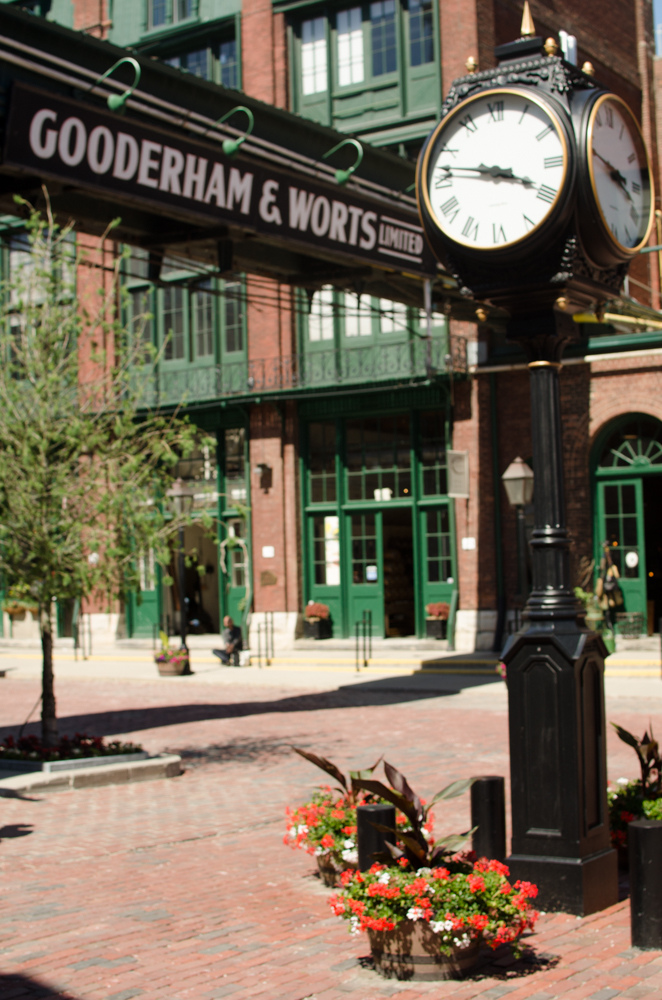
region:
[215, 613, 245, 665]
a man sitting on a step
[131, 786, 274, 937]
a red brick walk way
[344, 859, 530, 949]
a batch of red and white flowers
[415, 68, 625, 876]
a clock on a post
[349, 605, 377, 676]
a black hand rail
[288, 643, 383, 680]
a set of concrete step painted yellow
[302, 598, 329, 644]
a potted plant next to a building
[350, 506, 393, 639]
a green wood door to a building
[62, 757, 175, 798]
a concrete curb around a tree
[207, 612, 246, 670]
a man sitting down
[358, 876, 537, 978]
a round wood pot with flowers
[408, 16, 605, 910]
a clock on a black post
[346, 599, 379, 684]
a metal handrail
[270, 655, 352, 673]
concrete steps painted yellow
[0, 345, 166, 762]
a small tree with green leaves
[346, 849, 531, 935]
red and white flowers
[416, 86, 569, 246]
The clock facing more left and center than right.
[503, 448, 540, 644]
The lamp post by the door.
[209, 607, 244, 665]
The man sitting on the stairs.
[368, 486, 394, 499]
The white numbers above the door.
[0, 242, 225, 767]
The tree on the left.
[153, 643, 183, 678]
The potted plant next to the man.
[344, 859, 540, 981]
The potted plant in front of the post the clock is mounted on.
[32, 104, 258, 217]
The name GOODERHAM on the sign.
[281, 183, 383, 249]
The word WORTS on the sign.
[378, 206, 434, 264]
The word LIMITED on the sign.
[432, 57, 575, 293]
White clock face pointing to the left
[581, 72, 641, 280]
White clock facing the right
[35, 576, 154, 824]
Curbing around the tree in the parking lot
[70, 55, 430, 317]
Billboard hanging above the street in the lot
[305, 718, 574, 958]
Flowers planted at the base of the pole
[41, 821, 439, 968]
Brick sidewalk in front of the plants and the pole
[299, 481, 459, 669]
Large entry way in front of the store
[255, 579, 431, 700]
Stairs in front of the entry way of the store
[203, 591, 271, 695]
Man sitting on the steps outside of the building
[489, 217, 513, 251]
A number on a clock.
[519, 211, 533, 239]
A number on a clock.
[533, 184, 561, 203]
A number on a clock.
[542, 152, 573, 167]
A number on a clock.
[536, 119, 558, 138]
A number on a clock.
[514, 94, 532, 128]
A number on a clock.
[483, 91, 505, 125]
A number on a clock.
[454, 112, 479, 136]
A number on a clock.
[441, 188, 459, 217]
A number on a clock.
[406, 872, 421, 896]
flower in a pot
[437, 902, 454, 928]
flower in a pot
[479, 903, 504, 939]
flower in a pot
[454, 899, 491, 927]
flower in a pot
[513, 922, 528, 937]
flower in a pot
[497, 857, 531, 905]
flower in a pot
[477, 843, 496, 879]
flower in a pot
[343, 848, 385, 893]
flower in a pot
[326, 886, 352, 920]
flower in a pot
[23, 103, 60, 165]
A letter on a sign.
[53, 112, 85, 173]
A letter on a sign.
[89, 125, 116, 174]
A letter on a sign.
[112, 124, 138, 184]
A letter on a sign.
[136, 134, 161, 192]
A letter on a sign.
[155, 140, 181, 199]
A letter on a sign.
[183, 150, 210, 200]
A letter on a sign.